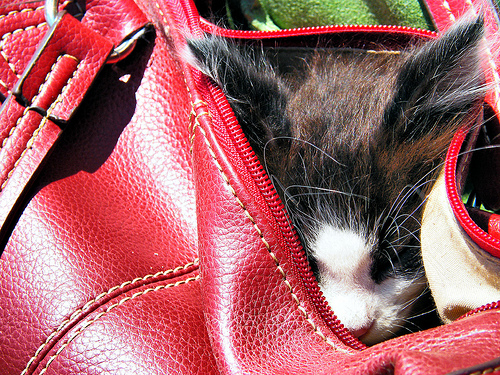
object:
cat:
[171, 16, 464, 334]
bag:
[0, 0, 500, 374]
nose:
[331, 311, 390, 339]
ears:
[390, 9, 489, 113]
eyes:
[364, 241, 415, 280]